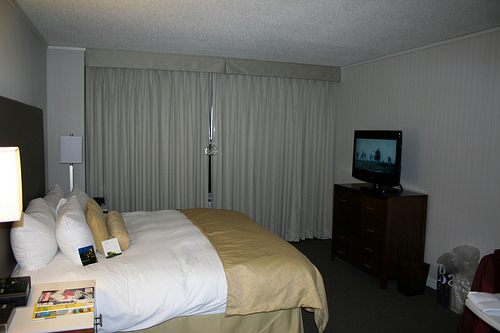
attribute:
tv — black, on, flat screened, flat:
[354, 131, 400, 183]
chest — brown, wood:
[333, 182, 426, 291]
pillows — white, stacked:
[10, 187, 126, 272]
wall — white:
[338, 32, 499, 281]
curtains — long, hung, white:
[84, 48, 337, 248]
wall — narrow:
[46, 51, 87, 205]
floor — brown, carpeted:
[290, 241, 467, 328]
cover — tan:
[180, 205, 321, 314]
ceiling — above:
[20, 6, 499, 66]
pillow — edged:
[13, 196, 61, 279]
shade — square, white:
[60, 138, 84, 168]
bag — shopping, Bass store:
[436, 254, 457, 305]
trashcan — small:
[397, 255, 431, 292]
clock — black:
[1, 277, 31, 310]